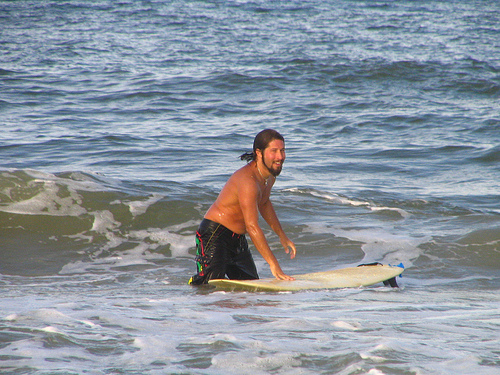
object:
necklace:
[257, 165, 273, 186]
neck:
[250, 159, 274, 182]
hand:
[280, 238, 297, 259]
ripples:
[1, 4, 499, 182]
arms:
[238, 182, 278, 265]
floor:
[134, 126, 289, 161]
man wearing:
[188, 218, 257, 283]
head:
[253, 129, 286, 176]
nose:
[276, 153, 283, 160]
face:
[264, 140, 286, 171]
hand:
[270, 263, 296, 280]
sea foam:
[8, 164, 498, 374]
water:
[0, 0, 500, 375]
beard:
[262, 156, 284, 177]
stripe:
[189, 230, 208, 285]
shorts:
[188, 217, 260, 285]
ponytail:
[238, 152, 253, 162]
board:
[208, 265, 405, 292]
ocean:
[0, 0, 500, 375]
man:
[194, 129, 296, 284]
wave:
[1, 158, 497, 290]